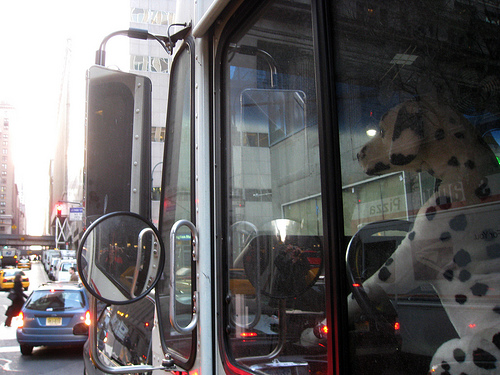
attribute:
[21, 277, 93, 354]
vehicle — light blue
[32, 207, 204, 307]
mirror — round, silver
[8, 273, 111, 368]
car — blue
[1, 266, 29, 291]
taxi — bright yellow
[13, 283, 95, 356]
car — blue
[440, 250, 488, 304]
spots — black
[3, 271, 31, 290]
vehicle — yellow